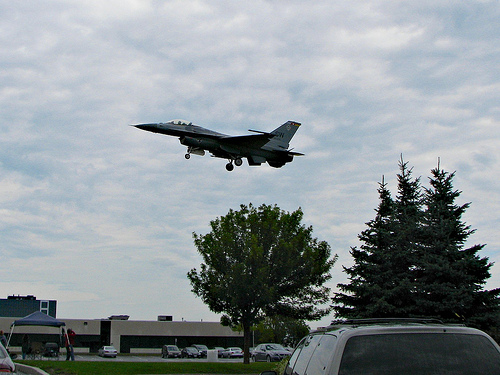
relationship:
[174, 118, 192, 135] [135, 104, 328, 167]
cockpit of airplane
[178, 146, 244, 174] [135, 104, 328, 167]
wheel of airplane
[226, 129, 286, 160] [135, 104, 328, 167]
wing of airplane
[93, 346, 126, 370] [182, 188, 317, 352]
car by tree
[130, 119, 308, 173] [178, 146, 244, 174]
airplane has wheel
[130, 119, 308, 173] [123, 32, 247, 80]
airplane in sky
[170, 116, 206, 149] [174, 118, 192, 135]
pilot in cockpit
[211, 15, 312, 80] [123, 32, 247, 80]
cloud in sky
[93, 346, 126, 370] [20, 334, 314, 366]
car in parking lot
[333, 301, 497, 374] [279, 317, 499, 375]
window on van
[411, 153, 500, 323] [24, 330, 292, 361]
evergreen next to parking lot